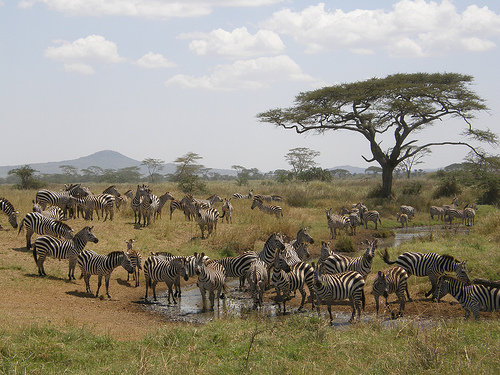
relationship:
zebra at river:
[141, 255, 191, 307] [145, 212, 472, 330]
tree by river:
[253, 71, 500, 197] [145, 212, 472, 330]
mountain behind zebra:
[63, 150, 155, 174] [141, 255, 191, 307]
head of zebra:
[266, 229, 287, 252] [141, 255, 191, 307]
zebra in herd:
[141, 255, 191, 307] [6, 183, 499, 322]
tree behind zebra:
[253, 71, 500, 197] [141, 255, 191, 307]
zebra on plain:
[141, 255, 191, 307] [2, 188, 334, 373]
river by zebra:
[145, 212, 472, 330] [141, 255, 191, 307]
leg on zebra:
[297, 285, 309, 310] [141, 255, 191, 307]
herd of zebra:
[6, 183, 499, 322] [141, 255, 191, 307]